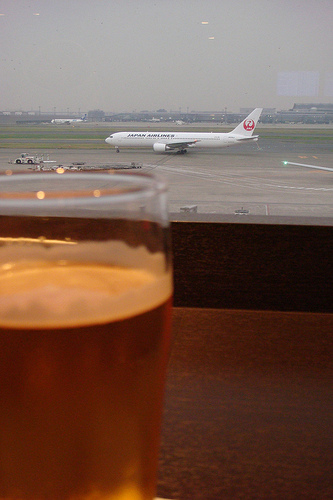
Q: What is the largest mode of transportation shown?
A: Plane.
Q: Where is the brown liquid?
A: In the glass.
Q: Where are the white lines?
A: Pavement.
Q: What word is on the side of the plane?
A: Japan Airlines.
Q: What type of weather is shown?
A: Gray and overcast.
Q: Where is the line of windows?
A: Along the side of the plane.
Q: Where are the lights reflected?
A: In the window.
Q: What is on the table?
A: Foamy beer glass.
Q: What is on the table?
A: Glass of beer with foamy head.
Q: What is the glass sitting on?
A: Wood table.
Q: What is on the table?
A: Full glass of beer.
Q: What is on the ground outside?
A: Airplane.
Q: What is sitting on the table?
A: Full glass of beer.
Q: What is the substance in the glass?
A: Brown beer.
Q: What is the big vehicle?
A: Plane.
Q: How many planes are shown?
A: One.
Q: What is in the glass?
A: Beer.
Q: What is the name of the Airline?
A: Japan Airlines.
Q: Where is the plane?
A: On the runway.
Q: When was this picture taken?
A: Daytime.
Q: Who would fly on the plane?
A: Travelers.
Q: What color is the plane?
A: White.